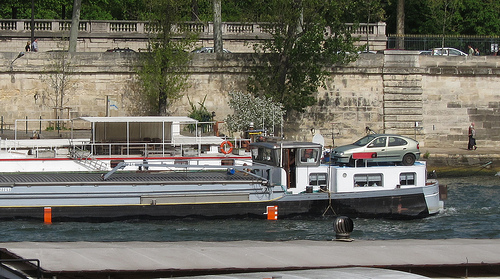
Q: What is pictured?
A: A ferry.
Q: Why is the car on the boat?
A: To cross to the other side.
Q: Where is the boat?
A: In the water.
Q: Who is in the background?
A: Pedestrians.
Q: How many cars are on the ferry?
A: 1.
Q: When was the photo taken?
A: Daylight.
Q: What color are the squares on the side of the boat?
A: Orange.